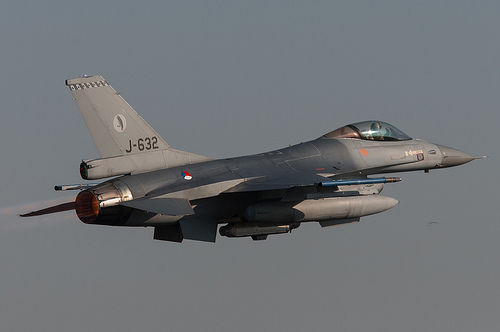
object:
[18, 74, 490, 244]
jet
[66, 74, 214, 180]
tail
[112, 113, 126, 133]
circle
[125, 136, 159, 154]
writing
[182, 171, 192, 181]
marking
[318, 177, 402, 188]
weapon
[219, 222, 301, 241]
weapon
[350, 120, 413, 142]
hatch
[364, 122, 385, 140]
pilot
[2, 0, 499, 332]
sky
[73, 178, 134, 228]
engine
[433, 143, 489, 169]
nose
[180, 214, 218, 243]
fin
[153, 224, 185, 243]
fin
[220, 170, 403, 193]
wing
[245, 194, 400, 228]
fuel tank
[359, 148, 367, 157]
spot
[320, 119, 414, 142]
cockpit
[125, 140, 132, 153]
letter